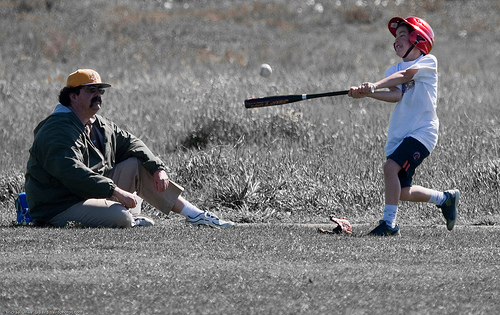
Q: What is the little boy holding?
A: A baseball bat.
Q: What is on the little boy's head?
A: A helmet.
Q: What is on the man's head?
A: A hat.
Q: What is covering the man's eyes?
A: Sunglasses.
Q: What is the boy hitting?
A: A ball.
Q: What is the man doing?
A: Sitting on the ground.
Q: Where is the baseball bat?
A: In the boy's hands.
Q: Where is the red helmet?
A: On the boy's head.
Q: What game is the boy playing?
A: Baseball.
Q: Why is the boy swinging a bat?
A: To hit ball.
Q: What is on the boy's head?
A: A helmet.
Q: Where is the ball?
A: In the air.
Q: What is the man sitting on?
A: Grass.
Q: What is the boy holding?
A: A bat.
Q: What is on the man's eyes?
A: Glasses.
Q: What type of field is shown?
A: Grass.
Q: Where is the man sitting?
A: Next to player.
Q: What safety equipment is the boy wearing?
A: Helmet.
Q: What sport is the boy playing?
A: Baseball.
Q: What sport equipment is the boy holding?
A: Bat.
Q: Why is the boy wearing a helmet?
A: To protect his head.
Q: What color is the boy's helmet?
A: Red.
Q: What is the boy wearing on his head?
A: A helmet.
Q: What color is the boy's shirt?
A: White.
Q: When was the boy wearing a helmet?
A: While he was playing baseball.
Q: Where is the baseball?
A: In the air.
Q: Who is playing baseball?
A: The little boy.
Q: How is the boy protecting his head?
A: By wearing a helmet.